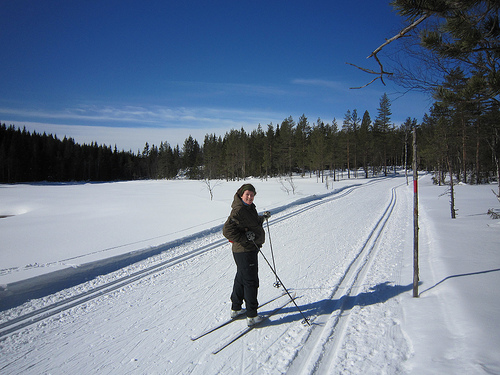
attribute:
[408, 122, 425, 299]
pole — tall, wooden, ski, large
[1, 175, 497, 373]
snow — fresh, heavy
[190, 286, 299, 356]
skis — covered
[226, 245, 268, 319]
pants — black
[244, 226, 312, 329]
poles — ski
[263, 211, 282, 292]
poles — ski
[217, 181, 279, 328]
skier — skiing, smiling, posing, dressed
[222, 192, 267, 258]
jacket — brown, heavy, green, large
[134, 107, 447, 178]
trees — lining, forested, green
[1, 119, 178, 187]
trees — lining, forested, green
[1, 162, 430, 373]
road — level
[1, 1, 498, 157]
sky — blue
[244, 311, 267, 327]
boots — ski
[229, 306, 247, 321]
boots — ski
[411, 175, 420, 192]
tape — red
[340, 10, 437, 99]
branch — hanging